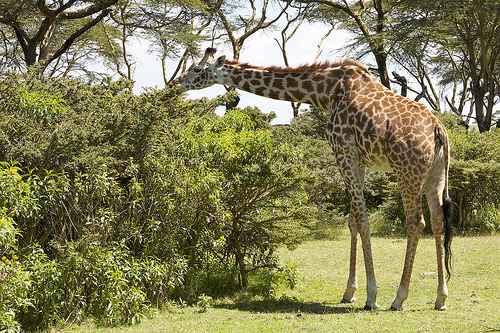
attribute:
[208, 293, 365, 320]
shadow — here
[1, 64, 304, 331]
bush — here, green, branched, leafy, thick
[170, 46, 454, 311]
giraffe — eating, standing, brown, tall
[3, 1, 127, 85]
tree — here, tall, brown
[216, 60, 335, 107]
neck — brown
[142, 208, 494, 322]
lawn — here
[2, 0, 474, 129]
sky — blue, white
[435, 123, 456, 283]
tail — black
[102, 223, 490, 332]
grass — green, small, short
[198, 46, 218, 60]
horns — small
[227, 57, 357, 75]
hair — brown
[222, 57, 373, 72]
mane — brown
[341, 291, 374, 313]
feet — white